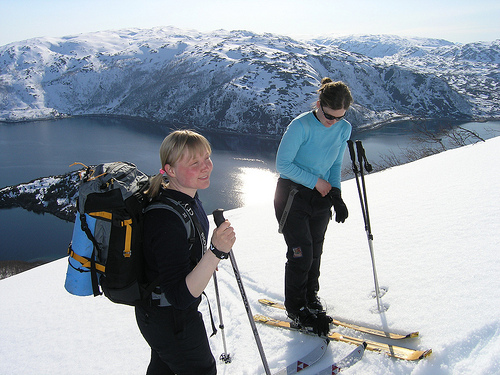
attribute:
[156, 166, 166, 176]
band — pink colored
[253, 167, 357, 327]
jeans — black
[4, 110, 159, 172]
water — calm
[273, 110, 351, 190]
shirt — blue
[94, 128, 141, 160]
water — calm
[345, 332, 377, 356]
ski — yellow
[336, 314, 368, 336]
ski — yellow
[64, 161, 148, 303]
backpack — blue, black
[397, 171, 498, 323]
snow — smooth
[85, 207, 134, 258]
strap — yellow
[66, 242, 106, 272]
strap — yellow